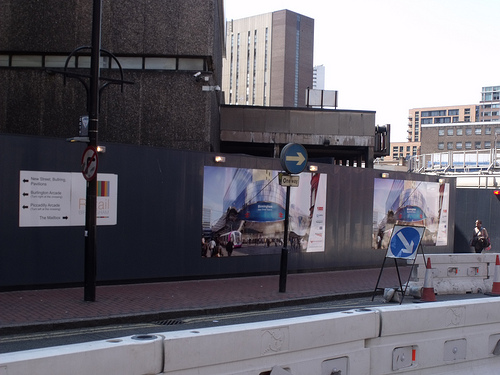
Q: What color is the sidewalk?
A: Brick red.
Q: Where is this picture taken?
A: City.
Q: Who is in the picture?
A: A man.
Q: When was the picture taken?
A: Daytime.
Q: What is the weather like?
A: Clear.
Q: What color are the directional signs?
A: Blue, white.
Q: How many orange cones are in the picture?
A: 2.